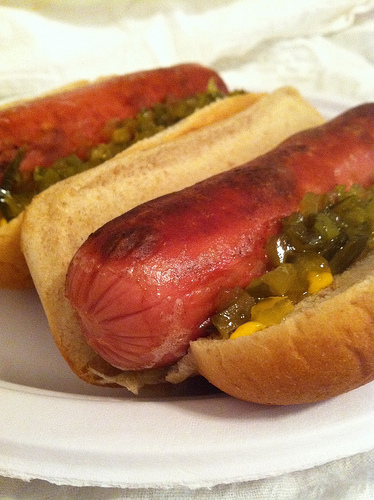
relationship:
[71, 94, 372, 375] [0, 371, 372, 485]
hotdog on plate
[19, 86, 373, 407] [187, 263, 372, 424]
hotdog on bun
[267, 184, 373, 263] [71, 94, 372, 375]
relish on hotdog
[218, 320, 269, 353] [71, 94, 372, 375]
mustard on hotdog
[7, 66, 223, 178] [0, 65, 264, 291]
hotdog and bun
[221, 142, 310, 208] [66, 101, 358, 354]
blister on hot dog